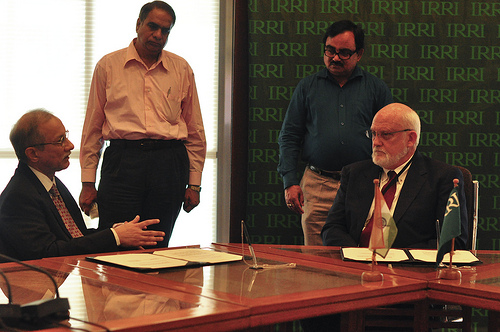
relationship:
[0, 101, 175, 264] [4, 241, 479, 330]
man at table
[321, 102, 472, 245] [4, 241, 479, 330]
man at table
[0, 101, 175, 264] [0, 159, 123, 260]
man wearing suit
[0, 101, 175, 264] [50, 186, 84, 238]
man wearing tie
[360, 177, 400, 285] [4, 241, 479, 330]
flag on top of table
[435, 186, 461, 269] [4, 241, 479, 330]
flag on top of table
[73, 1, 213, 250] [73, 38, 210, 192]
man wearing shirt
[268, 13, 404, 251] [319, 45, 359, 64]
man wearing glasses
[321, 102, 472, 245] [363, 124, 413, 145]
man wearing glasses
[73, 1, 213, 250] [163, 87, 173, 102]
man has pen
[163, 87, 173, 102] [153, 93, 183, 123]
pen in pocket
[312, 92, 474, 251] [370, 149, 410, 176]
man has beard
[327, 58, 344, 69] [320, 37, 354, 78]
mustache on face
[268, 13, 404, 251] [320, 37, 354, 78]
man has face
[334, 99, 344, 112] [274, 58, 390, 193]
button on shirt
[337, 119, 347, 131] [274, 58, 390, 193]
button on shirt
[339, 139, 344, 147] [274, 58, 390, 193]
button on shirt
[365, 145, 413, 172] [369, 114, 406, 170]
beard on face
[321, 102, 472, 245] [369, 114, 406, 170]
man has face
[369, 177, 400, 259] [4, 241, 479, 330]
flag on table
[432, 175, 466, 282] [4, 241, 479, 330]
flag on table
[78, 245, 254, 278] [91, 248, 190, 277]
booklet with papers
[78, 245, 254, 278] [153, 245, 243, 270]
booklet with papers